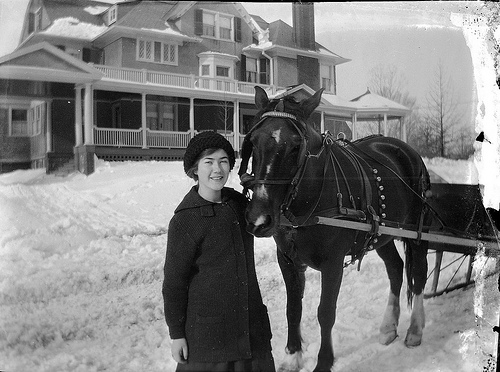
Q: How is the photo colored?
A: Black and white.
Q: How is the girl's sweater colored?
A: Black.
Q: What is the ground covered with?
A: Snow.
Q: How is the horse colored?
A: Black.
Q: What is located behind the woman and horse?
A: A large house.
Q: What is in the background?
A: A large house.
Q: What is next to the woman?
A: A horse.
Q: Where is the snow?
A: On the ground.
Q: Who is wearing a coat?
A: A woman.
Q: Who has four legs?
A: The horse.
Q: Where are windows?
A: On the house.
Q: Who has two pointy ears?
A: A horse.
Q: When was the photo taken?
A: During the daytime.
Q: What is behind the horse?
A: A carriage.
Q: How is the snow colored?
A: White.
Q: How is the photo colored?
A: Black and white.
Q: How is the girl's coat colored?
A: Black.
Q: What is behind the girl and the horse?
A: A huge house.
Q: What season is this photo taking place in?
A: Winter.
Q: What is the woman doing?
A: Standing.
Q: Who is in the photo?
A: A woman.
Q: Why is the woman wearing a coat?
A: To keep warm.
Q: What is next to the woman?
A: A horse.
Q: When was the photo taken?
A: Day time.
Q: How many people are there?
A: One.